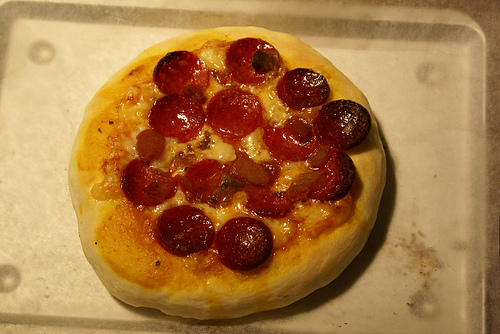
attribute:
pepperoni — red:
[215, 216, 272, 271]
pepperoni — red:
[154, 205, 214, 257]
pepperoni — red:
[182, 156, 230, 202]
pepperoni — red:
[120, 159, 178, 206]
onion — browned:
[125, 122, 170, 160]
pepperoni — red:
[202, 90, 283, 144]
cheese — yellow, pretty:
[211, 138, 239, 165]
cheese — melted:
[185, 127, 245, 172]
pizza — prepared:
[58, 14, 399, 331]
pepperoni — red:
[311, 99, 371, 149]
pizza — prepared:
[39, 30, 411, 300]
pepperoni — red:
[164, 91, 328, 165]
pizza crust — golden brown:
[66, 21, 421, 326]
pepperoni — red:
[244, 185, 294, 217]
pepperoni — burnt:
[122, 37, 375, 271]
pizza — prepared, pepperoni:
[70, 27, 389, 319]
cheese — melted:
[202, 136, 234, 161]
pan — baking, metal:
[0, 5, 494, 330]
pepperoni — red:
[322, 105, 374, 147]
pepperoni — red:
[274, 67, 329, 108]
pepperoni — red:
[212, 91, 259, 135]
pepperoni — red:
[220, 217, 270, 269]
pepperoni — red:
[124, 155, 179, 203]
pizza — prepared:
[92, 65, 388, 268]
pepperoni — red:
[222, 215, 264, 266]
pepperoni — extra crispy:
[313, 97, 367, 143]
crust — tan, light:
[91, 180, 219, 306]